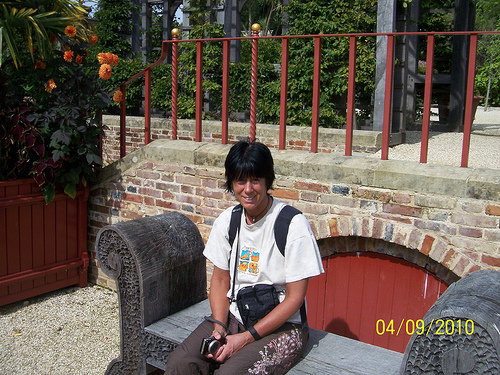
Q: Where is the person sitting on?
A: A bench.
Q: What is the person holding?
A: A camera.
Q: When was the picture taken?
A: Daytime.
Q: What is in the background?
A: A fence.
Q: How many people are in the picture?
A: One.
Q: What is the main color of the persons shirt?
A: White.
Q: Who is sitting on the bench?
A: A woman.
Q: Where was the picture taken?
A: Close to a bench.